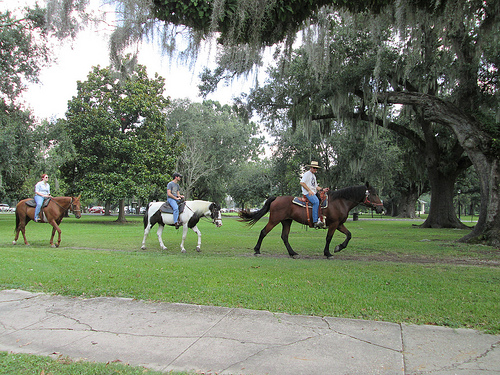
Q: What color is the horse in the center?
A: White and black.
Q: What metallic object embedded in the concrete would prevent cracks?
A: Rebar.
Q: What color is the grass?
A: Green.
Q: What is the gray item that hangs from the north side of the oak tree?
A: Moss.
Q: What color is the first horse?
A: Brown.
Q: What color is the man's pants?
A: Blue.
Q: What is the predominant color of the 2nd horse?
A: White.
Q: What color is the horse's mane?
A: Black.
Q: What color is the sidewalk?
A: Grey.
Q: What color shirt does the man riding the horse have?
A: White.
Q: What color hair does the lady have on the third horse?
A: Red.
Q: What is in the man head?
A: Hat.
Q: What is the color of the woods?
A: Brown.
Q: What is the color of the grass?
A: Green.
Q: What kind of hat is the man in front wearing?
A: Cowboy hat.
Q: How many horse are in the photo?
A: 3.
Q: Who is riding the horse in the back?
A: A woman.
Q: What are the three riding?
A: Horses.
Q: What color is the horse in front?
A: Brown.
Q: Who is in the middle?
A: A man.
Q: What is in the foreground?
A: A sidewalk.